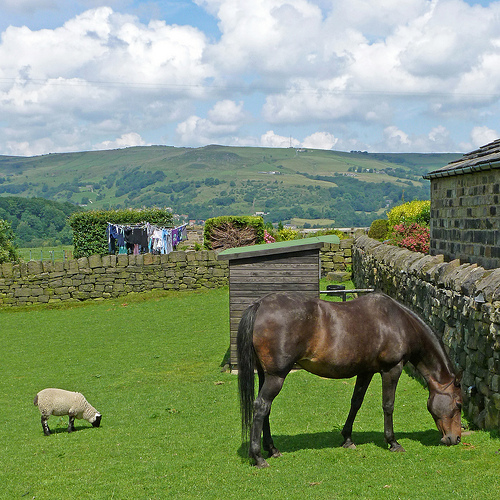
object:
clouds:
[42, 4, 394, 109]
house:
[420, 137, 500, 267]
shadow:
[236, 428, 451, 468]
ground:
[66, 463, 465, 487]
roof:
[216, 235, 340, 261]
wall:
[441, 184, 494, 254]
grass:
[0, 297, 110, 499]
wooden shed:
[217, 234, 337, 374]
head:
[426, 383, 464, 446]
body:
[299, 299, 369, 376]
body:
[42, 387, 87, 415]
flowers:
[385, 200, 431, 225]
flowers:
[383, 218, 434, 253]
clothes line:
[101, 217, 190, 232]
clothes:
[107, 222, 189, 256]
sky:
[2, 0, 497, 161]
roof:
[423, 137, 500, 178]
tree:
[69, 208, 172, 258]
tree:
[307, 186, 313, 193]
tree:
[227, 181, 234, 188]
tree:
[81, 197, 88, 205]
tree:
[332, 212, 365, 227]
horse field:
[230, 277, 458, 470]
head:
[90, 410, 104, 428]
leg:
[248, 339, 296, 457]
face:
[93, 416, 101, 427]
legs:
[380, 365, 403, 441]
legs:
[338, 374, 371, 436]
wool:
[48, 390, 70, 401]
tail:
[235, 304, 256, 460]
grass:
[271, 403, 498, 497]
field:
[6, 299, 498, 498]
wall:
[71, 247, 242, 297]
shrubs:
[270, 188, 301, 206]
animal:
[236, 288, 464, 466]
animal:
[33, 388, 101, 436]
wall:
[351, 232, 499, 427]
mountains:
[1, 143, 466, 225]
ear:
[454, 370, 464, 386]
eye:
[456, 402, 462, 410]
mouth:
[441, 433, 457, 446]